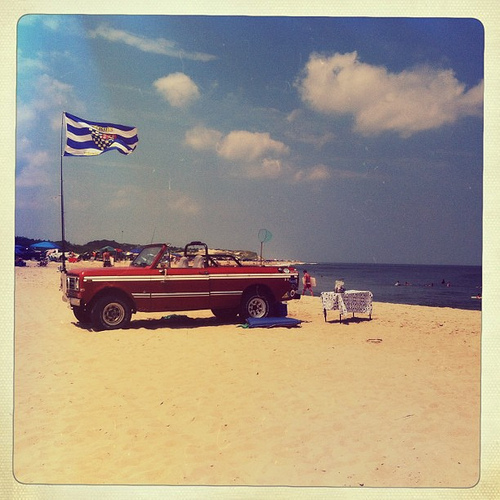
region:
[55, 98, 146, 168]
a blue and white flag in breeze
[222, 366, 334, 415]
sand on the beach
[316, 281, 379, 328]
a table cloth on a table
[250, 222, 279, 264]
a fishing net in the air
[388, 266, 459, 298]
people in the ocean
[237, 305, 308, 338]
a blue raft near a truck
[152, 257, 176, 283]
the left mirror of a truck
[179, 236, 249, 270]
a roll bar on a truck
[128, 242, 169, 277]
the front window of a truck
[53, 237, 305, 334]
a red vehicle parked on the beach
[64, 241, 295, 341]
truck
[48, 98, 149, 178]
flag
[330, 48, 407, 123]
white clouds in blue sky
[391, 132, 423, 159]
white clouds in blue sky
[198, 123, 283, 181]
white clouds in blue sky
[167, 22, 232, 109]
white clouds in blue sky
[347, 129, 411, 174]
white clouds in blue sky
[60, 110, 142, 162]
Blue and white striped flag with emblem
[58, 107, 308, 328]
Flag attached to the front of a car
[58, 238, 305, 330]
Red vehicle on the beach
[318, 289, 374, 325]
Table set up on the beach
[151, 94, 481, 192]
Puffy clouds in the sky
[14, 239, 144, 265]
Umbrellas in the background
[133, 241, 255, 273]
No roof on the vehicle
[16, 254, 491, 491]
Lots of sand on the beach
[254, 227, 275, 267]
Net sticking up in the back of the vehicle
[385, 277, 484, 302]
A bunch of people in the water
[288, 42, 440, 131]
white cloud in sky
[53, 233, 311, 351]
truck on the sand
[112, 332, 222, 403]
sand under the car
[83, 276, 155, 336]
tire on the car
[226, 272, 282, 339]
back tire of car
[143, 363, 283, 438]
footprints in the sand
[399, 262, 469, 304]
people in the water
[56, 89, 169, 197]
blue and white flag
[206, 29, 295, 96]
blue sky above water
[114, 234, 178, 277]
window on front of car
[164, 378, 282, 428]
A fine white sand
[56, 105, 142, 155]
A flag with blue and white stripe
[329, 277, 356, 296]
A bag on the table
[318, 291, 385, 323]
Small table on the beach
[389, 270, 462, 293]
People swimming in the beach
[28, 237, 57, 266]
A big blue umbrella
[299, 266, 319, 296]
A man with a white board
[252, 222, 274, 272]
A green fish net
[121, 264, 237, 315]
A white dash of lines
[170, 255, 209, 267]
Gray chairs on the car